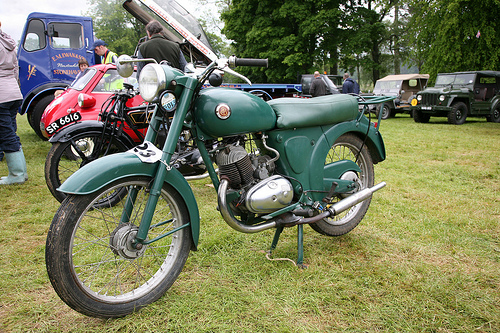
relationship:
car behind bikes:
[40, 63, 203, 212] [44, 63, 385, 317]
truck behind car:
[6, 11, 316, 118] [40, 56, 202, 145]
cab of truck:
[410, 54, 498, 125] [11, 4, 311, 143]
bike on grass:
[41, 46, 398, 329] [0, 113, 497, 330]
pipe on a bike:
[296, 181, 387, 226] [43, 58, 387, 316]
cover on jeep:
[366, 67, 432, 121] [408, 70, 499, 125]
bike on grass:
[42, 55, 399, 319] [0, 113, 497, 330]